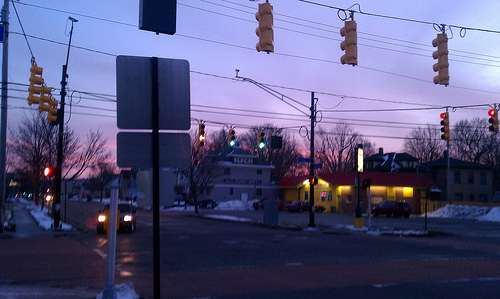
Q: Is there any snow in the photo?
A: Yes, there is snow.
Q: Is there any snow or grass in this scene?
A: Yes, there is snow.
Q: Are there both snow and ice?
A: No, there is snow but no ice.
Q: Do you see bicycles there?
A: No, there are no bicycles.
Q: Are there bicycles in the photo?
A: No, there are no bicycles.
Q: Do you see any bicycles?
A: No, there are no bicycles.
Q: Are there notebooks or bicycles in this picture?
A: No, there are no bicycles or notebooks.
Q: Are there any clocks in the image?
A: No, there are no clocks.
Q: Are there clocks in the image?
A: No, there are no clocks.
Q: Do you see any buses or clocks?
A: No, there are no clocks or buses.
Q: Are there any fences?
A: No, there are no fences.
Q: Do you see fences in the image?
A: No, there are no fences.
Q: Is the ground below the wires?
A: Yes, the ground is below the wires.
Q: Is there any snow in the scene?
A: Yes, there is snow.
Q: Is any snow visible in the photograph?
A: Yes, there is snow.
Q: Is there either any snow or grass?
A: Yes, there is snow.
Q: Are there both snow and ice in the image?
A: No, there is snow but no ice.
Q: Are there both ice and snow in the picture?
A: No, there is snow but no ice.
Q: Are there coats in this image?
A: No, there are no coats.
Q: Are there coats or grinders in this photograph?
A: No, there are no coats or grinders.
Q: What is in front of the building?
A: The snow is in front of the building.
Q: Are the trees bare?
A: Yes, the trees are bare.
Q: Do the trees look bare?
A: Yes, the trees are bare.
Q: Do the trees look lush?
A: No, the trees are bare.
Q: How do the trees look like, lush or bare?
A: The trees are bare.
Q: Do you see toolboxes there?
A: No, there are no toolboxes.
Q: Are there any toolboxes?
A: No, there are no toolboxes.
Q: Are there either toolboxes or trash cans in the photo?
A: No, there are no toolboxes or trash cans.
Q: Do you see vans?
A: No, there are no vans.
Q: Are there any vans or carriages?
A: No, there are no vans or carriages.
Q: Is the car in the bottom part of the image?
A: Yes, the car is in the bottom of the image.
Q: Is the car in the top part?
A: No, the car is in the bottom of the image.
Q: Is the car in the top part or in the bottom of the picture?
A: The car is in the bottom of the image.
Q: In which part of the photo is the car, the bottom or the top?
A: The car is in the bottom of the image.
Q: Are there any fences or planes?
A: No, there are no fences or planes.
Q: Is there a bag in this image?
A: No, there are no bags.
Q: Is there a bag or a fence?
A: No, there are no bags or fences.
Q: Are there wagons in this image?
A: No, there are no wagons.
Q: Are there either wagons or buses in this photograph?
A: No, there are no wagons or buses.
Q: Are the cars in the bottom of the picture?
A: Yes, the cars are in the bottom of the image.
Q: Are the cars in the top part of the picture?
A: No, the cars are in the bottom of the image.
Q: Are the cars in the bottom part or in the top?
A: The cars are in the bottom of the image.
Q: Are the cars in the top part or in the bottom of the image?
A: The cars are in the bottom of the image.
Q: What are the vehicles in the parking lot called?
A: The vehicles are cars.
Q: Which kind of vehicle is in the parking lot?
A: The vehicles are cars.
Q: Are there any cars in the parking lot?
A: Yes, there are cars in the parking lot.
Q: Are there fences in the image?
A: No, there are no fences.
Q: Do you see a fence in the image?
A: No, there are no fences.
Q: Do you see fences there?
A: No, there are no fences.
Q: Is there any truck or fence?
A: No, there are no fences or trucks.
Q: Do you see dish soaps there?
A: No, there are no dish soaps.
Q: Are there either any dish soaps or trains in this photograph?
A: No, there are no dish soaps or trains.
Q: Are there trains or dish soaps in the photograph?
A: No, there are no dish soaps or trains.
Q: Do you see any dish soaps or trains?
A: No, there are no dish soaps or trains.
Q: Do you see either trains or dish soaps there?
A: No, there are no dish soaps or trains.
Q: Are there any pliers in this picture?
A: No, there are no pliers.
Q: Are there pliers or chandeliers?
A: No, there are no pliers or chandeliers.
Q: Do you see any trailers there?
A: No, there are no trailers.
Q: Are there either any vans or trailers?
A: No, there are no trailers or vans.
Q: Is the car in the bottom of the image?
A: Yes, the car is in the bottom of the image.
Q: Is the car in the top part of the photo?
A: No, the car is in the bottom of the image.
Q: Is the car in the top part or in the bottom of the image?
A: The car is in the bottom of the image.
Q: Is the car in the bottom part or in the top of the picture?
A: The car is in the bottom of the image.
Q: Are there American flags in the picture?
A: No, there are no American flags.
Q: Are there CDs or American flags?
A: No, there are no American flags or cds.